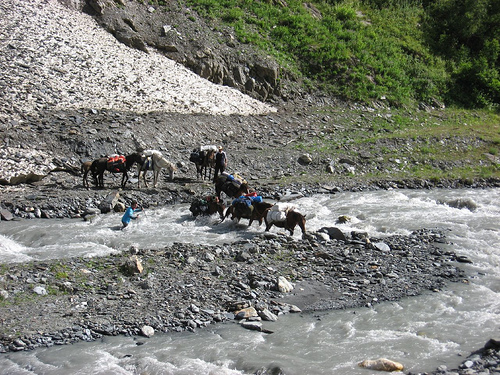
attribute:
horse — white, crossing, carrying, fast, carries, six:
[138, 145, 175, 184]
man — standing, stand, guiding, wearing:
[104, 185, 140, 245]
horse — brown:
[79, 139, 154, 194]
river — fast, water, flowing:
[51, 192, 132, 295]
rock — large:
[22, 185, 98, 245]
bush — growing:
[382, 81, 425, 108]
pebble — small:
[360, 125, 431, 173]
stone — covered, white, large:
[138, 60, 261, 148]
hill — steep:
[211, 48, 347, 104]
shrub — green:
[315, 52, 387, 104]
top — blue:
[228, 159, 273, 216]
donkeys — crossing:
[32, 116, 325, 242]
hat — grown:
[121, 198, 146, 209]